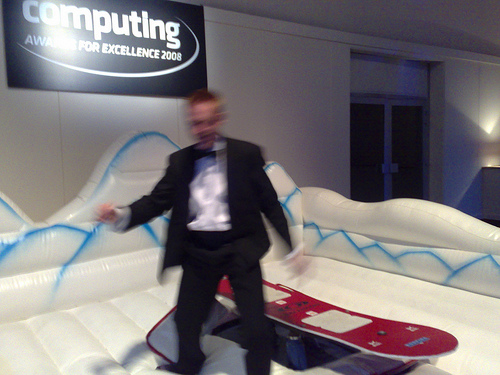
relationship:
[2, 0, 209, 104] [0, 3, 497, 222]
sign on wall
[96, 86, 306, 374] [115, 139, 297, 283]
man has on jacket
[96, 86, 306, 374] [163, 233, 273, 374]
man has on pants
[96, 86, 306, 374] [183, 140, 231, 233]
man has on shirt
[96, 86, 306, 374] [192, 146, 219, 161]
man wearing tie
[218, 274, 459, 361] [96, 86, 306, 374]
snowboard behind man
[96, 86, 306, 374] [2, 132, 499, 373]
man in inflatable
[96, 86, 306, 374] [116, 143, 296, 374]
man in tux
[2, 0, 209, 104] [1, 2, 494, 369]
sign for event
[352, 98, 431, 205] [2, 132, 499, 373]
door behind inflatable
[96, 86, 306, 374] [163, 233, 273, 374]
man in pants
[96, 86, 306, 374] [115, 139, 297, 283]
man in jacket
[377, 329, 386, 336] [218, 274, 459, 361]
bolt on snowboard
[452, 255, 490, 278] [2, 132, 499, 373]
line on inflatable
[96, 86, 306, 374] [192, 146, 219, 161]
man in tie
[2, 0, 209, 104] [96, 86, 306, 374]
sign above man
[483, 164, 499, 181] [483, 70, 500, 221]
light in corner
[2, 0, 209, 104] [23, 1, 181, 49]
sign says computing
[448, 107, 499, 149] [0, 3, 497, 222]
shadow on wall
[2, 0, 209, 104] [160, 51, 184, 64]
sign says 2008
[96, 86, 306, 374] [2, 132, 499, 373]
man on inflatable